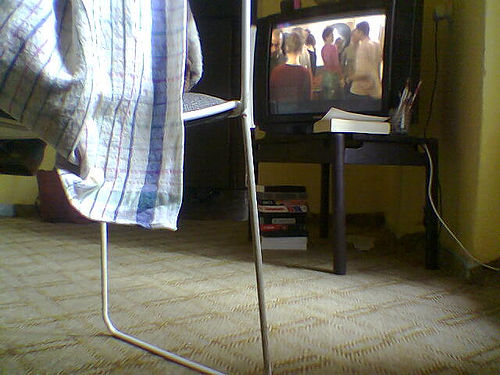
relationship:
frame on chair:
[96, 3, 283, 363] [98, 1, 301, 373]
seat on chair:
[164, 85, 232, 125] [0, 0, 272, 374]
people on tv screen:
[320, 23, 387, 83] [267, 10, 384, 117]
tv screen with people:
[267, 10, 384, 117] [320, 23, 387, 83]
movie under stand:
[255, 201, 317, 216] [249, 131, 440, 274]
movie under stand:
[256, 223, 304, 233] [249, 131, 440, 274]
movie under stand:
[254, 192, 306, 197] [249, 131, 440, 274]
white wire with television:
[420, 145, 494, 280] [255, 7, 427, 136]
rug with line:
[293, 318, 360, 370] [295, 320, 318, 335]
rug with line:
[293, 318, 360, 370] [346, 335, 362, 350]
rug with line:
[293, 318, 360, 370] [281, 352, 309, 369]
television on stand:
[255, 7, 427, 136] [243, 124, 456, 291]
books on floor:
[254, 181, 311, 253] [1, 216, 499, 373]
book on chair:
[310, 110, 392, 135] [318, 124, 447, 278]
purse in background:
[31, 167, 87, 225] [13, 14, 473, 255]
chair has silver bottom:
[0, 0, 272, 374] [99, 123, 274, 373]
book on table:
[313, 105, 392, 135] [238, 127, 440, 276]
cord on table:
[415, 136, 498, 276] [216, 122, 446, 277]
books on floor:
[254, 179, 312, 259] [1, 216, 499, 373]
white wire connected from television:
[420, 145, 494, 280] [255, 7, 427, 136]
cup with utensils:
[394, 100, 412, 130] [390, 74, 449, 134]